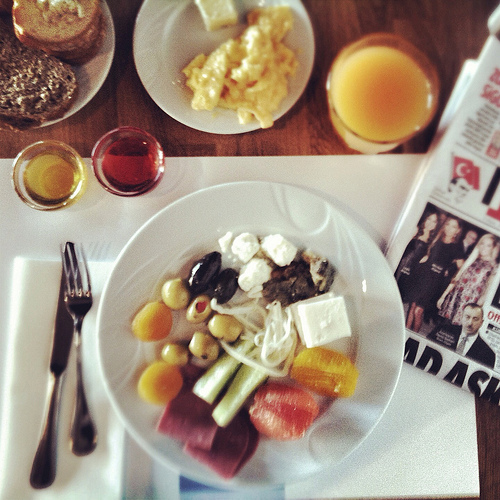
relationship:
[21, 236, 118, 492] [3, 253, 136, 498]
silverware on napkin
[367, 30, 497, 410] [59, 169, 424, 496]
newspaper next plate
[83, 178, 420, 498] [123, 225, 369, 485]
plate has foot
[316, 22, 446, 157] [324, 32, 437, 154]
glass has orange juice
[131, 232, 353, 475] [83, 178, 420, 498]
food on plate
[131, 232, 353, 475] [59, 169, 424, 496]
food on plate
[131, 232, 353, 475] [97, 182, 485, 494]
food on plate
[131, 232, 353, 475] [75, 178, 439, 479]
food on plate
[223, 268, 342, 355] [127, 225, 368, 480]
food on plate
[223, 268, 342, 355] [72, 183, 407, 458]
food on plate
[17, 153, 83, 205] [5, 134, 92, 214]
liquid in cup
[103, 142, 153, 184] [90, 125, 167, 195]
liquid in cup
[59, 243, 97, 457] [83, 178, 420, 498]
fork on plate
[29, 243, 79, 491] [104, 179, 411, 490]
knife near plate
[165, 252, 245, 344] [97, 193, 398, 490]
olives on plate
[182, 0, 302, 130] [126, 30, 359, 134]
food sitting on plate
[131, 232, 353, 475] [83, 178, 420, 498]
food sitting on plate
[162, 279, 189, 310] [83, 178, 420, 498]
olive on a plate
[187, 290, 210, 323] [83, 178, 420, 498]
olive on a plate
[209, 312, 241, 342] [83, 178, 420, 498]
olive on a plate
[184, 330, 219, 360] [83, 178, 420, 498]
olive on a plate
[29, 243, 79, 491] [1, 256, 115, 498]
knife on a napkin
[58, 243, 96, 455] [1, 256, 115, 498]
fork on a napkin